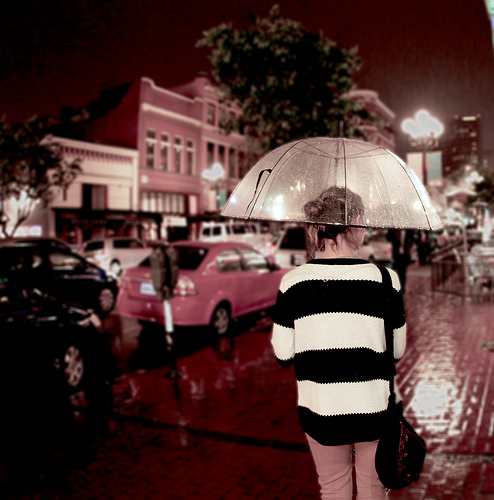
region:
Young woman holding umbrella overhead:
[221, 134, 444, 498]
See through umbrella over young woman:
[222, 134, 445, 232]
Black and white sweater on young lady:
[268, 254, 404, 447]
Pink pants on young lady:
[308, 434, 384, 498]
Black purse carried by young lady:
[372, 268, 427, 491]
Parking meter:
[145, 240, 178, 377]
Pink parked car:
[121, 237, 289, 335]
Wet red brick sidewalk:
[113, 275, 493, 498]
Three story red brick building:
[139, 69, 274, 235]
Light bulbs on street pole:
[402, 108, 444, 143]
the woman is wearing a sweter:
[268, 253, 407, 435]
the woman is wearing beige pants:
[304, 429, 400, 497]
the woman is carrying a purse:
[371, 264, 426, 491]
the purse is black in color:
[375, 259, 430, 487]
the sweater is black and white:
[272, 255, 407, 442]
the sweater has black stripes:
[270, 259, 409, 443]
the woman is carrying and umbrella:
[219, 133, 444, 226]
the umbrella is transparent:
[216, 136, 444, 233]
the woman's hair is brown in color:
[306, 187, 364, 247]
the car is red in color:
[118, 243, 302, 334]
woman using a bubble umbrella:
[208, 120, 454, 376]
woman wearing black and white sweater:
[237, 242, 426, 449]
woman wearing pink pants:
[293, 396, 448, 498]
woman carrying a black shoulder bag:
[246, 180, 450, 492]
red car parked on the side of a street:
[115, 211, 290, 338]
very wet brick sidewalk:
[71, 294, 483, 493]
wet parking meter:
[135, 234, 215, 377]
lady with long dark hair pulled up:
[297, 171, 394, 275]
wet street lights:
[400, 82, 477, 273]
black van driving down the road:
[0, 226, 144, 319]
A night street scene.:
[1, 0, 492, 497]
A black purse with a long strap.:
[372, 261, 428, 491]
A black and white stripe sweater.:
[274, 254, 404, 440]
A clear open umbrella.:
[219, 120, 446, 233]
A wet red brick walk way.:
[98, 415, 298, 498]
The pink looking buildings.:
[1, 71, 248, 238]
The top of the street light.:
[399, 108, 457, 146]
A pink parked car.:
[118, 240, 274, 335]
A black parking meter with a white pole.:
[145, 243, 193, 410]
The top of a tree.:
[197, 1, 362, 141]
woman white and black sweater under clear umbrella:
[219, 118, 457, 497]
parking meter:
[136, 245, 203, 367]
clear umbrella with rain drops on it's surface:
[213, 119, 450, 239]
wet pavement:
[426, 310, 480, 429]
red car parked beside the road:
[115, 238, 282, 341]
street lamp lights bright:
[395, 96, 457, 175]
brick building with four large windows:
[140, 74, 210, 215]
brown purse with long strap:
[363, 252, 427, 499]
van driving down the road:
[7, 232, 130, 314]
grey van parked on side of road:
[82, 228, 157, 278]